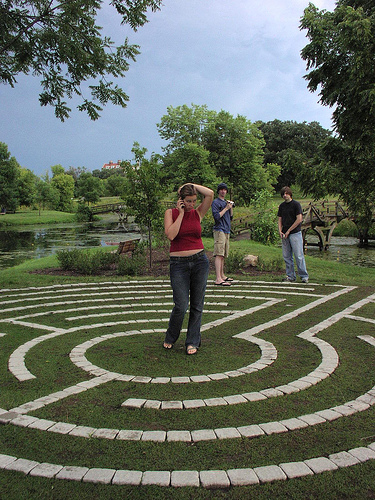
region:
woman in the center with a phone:
[210, 185, 233, 284]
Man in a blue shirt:
[212, 183, 237, 285]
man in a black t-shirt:
[275, 185, 311, 283]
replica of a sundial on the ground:
[5, 276, 373, 488]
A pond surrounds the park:
[4, 221, 143, 250]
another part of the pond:
[303, 235, 374, 261]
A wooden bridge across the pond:
[237, 200, 354, 251]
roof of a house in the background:
[101, 158, 137, 173]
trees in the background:
[0, 152, 71, 212]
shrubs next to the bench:
[55, 250, 140, 276]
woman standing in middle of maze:
[153, 169, 216, 379]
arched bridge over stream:
[60, 195, 168, 234]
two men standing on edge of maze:
[211, 174, 316, 303]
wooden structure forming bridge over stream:
[235, 191, 366, 253]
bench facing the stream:
[71, 219, 146, 261]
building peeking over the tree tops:
[90, 146, 136, 181]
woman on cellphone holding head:
[156, 171, 220, 225]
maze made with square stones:
[120, 381, 278, 414]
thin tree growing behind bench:
[101, 141, 162, 273]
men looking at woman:
[162, 173, 304, 290]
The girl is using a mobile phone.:
[147, 175, 228, 360]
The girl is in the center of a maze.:
[0, 281, 373, 498]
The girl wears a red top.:
[163, 200, 205, 254]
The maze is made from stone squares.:
[0, 282, 373, 498]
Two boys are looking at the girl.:
[204, 175, 312, 292]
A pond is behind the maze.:
[0, 211, 140, 277]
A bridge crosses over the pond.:
[79, 198, 159, 223]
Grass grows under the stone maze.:
[0, 280, 373, 498]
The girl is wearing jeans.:
[158, 245, 210, 343]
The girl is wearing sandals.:
[156, 334, 202, 361]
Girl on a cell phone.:
[132, 174, 216, 374]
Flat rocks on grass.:
[87, 421, 264, 491]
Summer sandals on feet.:
[137, 328, 226, 365]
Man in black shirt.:
[268, 166, 318, 312]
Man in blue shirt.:
[207, 168, 242, 297]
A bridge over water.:
[70, 165, 173, 238]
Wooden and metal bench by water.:
[45, 231, 155, 278]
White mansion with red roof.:
[59, 147, 162, 199]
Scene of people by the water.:
[19, 105, 320, 401]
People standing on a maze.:
[1, 174, 353, 496]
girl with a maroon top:
[163, 178, 214, 352]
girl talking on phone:
[159, 175, 219, 356]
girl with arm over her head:
[158, 176, 219, 358]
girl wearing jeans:
[159, 178, 214, 357]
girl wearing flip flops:
[153, 177, 216, 354]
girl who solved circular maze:
[159, 177, 214, 359]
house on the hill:
[96, 150, 144, 176]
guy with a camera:
[210, 182, 236, 289]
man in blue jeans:
[276, 186, 309, 286]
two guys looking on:
[212, 182, 305, 291]